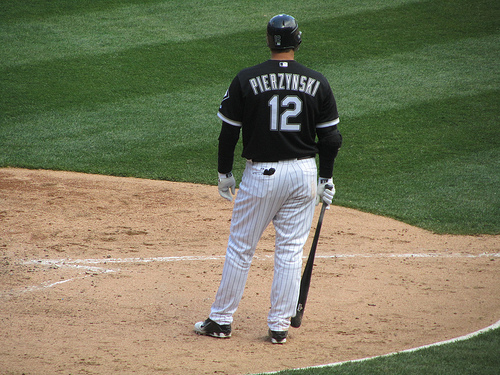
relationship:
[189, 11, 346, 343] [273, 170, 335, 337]
baseball player holding baseball bat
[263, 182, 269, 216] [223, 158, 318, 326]
stripe on pants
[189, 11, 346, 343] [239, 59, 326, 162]
baseball player has back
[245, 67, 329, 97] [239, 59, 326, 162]
letters on back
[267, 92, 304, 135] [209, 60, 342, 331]
12 on uniform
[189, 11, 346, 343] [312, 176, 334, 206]
baseball player wearing glove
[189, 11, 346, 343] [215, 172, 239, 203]
baseball player wearing hand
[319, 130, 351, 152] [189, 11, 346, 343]
elbow of baseball player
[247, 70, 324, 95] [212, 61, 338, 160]
letters on back of jersey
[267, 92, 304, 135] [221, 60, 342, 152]
12 on back of jersey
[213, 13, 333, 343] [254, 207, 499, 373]
baseball player on baseball infield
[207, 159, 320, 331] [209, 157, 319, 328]
baseball pants with stripes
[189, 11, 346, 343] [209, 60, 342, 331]
baseball player wearing uniform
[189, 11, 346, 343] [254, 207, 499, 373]
baseball player in baseball infield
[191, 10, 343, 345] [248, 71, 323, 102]
jersey has letters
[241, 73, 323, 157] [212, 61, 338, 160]
12 on jersey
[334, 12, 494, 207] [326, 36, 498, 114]
grass with stripe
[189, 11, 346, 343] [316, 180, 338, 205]
baseball player wearing gloves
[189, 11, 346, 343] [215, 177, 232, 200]
baseball player wearing gloves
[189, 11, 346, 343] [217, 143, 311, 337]
baseball player wearing pants